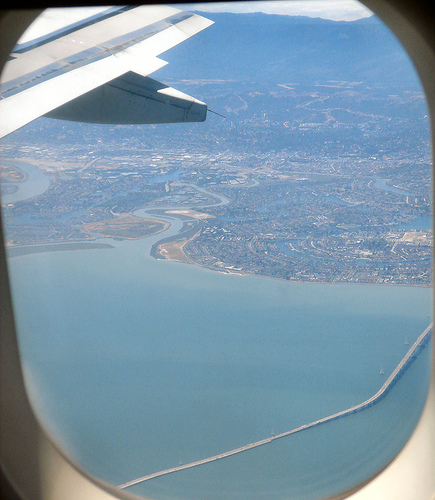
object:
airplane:
[0, 0, 227, 139]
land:
[0, 0, 435, 287]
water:
[0, 160, 435, 500]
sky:
[276, 0, 369, 18]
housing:
[40, 76, 208, 126]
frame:
[19, 367, 133, 500]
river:
[0, 161, 435, 500]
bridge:
[110, 322, 435, 492]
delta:
[0, 124, 430, 312]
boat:
[404, 342, 409, 345]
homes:
[253, 157, 402, 272]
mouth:
[104, 237, 168, 251]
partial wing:
[0, 0, 215, 143]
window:
[0, 0, 434, 500]